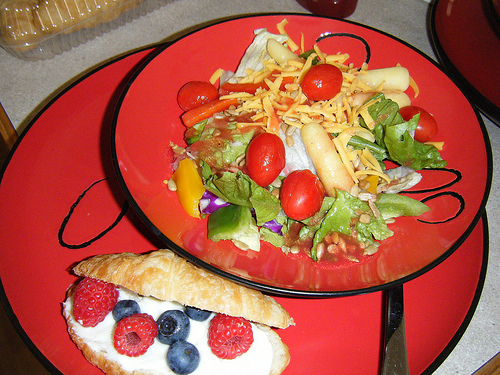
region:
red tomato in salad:
[281, 170, 323, 222]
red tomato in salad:
[246, 131, 288, 185]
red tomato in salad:
[175, 72, 221, 109]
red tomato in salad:
[301, 63, 345, 99]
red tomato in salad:
[405, 104, 437, 145]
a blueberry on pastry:
[166, 340, 201, 372]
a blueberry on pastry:
[156, 313, 193, 344]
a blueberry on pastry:
[113, 297, 141, 319]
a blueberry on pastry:
[184, 304, 214, 323]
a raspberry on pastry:
[70, 274, 115, 330]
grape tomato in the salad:
[237, 122, 287, 194]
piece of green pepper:
[198, 191, 253, 255]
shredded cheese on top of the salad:
[191, 36, 401, 184]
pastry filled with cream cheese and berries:
[53, 239, 299, 374]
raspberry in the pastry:
[208, 310, 253, 361]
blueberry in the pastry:
[166, 340, 198, 374]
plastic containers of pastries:
[2, 2, 182, 65]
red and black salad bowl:
[98, 5, 496, 303]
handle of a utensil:
[376, 285, 413, 373]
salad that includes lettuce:
[166, 14, 444, 267]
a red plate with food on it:
[92, 15, 499, 325]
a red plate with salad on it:
[110, 28, 449, 287]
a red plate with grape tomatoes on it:
[156, 66, 413, 243]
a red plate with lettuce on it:
[138, 57, 421, 254]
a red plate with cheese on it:
[166, 48, 465, 263]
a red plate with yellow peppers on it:
[127, 78, 314, 279]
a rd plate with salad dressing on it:
[177, 77, 446, 297]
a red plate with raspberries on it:
[18, 196, 259, 368]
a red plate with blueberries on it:
[29, 225, 231, 367]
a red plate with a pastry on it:
[6, 184, 233, 368]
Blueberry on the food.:
[165, 339, 201, 373]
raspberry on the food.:
[112, 308, 158, 360]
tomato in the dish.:
[277, 167, 321, 218]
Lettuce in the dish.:
[369, 93, 447, 175]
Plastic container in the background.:
[2, 1, 144, 55]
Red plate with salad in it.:
[105, 8, 492, 305]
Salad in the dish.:
[165, 25, 447, 265]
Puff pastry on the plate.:
[60, 240, 299, 373]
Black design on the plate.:
[42, 164, 134, 254]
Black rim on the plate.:
[107, 11, 494, 305]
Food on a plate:
[145, 18, 472, 262]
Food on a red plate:
[164, 14, 460, 276]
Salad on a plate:
[167, 38, 457, 266]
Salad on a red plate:
[141, 17, 461, 264]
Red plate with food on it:
[146, 36, 499, 251]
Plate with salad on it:
[132, 12, 481, 274]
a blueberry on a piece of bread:
[161, 344, 203, 366]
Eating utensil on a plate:
[378, 295, 407, 372]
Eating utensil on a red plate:
[377, 295, 419, 368]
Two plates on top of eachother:
[30, 60, 155, 202]